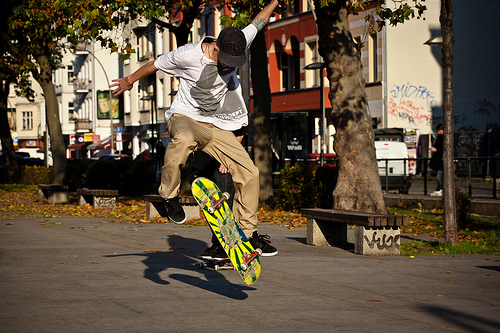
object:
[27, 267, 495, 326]
ground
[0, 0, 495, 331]
photo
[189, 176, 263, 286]
skateboard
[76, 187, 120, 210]
bench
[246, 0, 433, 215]
tree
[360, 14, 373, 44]
stem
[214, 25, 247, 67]
cap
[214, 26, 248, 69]
head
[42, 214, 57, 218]
leaves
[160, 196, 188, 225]
shoe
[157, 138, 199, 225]
leg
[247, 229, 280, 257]
shoe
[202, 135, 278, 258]
leg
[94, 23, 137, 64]
stem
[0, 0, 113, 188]
tree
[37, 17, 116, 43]
branches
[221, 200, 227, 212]
lines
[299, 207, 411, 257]
bench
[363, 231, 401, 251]
graffiti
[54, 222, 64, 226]
leaves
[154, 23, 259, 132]
shirt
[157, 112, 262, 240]
pants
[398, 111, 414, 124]
graffiti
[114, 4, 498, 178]
building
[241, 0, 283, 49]
arm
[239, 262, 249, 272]
wheel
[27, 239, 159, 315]
area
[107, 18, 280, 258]
boy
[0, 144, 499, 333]
park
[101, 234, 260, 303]
shadow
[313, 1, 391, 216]
trunk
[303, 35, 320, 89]
window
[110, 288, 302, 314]
cement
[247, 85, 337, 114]
ledge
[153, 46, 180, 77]
sleeve